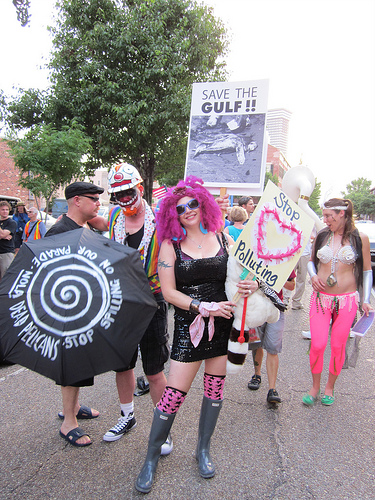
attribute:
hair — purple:
[156, 177, 223, 241]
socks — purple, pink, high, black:
[156, 371, 227, 418]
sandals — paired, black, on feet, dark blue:
[55, 404, 102, 447]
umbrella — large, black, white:
[0, 225, 160, 383]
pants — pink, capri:
[307, 291, 358, 375]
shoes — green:
[302, 389, 336, 409]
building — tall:
[264, 103, 295, 158]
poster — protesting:
[226, 180, 318, 303]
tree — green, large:
[10, 0, 233, 208]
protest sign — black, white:
[223, 178, 314, 313]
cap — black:
[62, 182, 105, 200]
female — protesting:
[299, 196, 373, 405]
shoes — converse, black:
[102, 408, 175, 456]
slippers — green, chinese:
[300, 388, 334, 411]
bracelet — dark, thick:
[187, 297, 201, 318]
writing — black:
[231, 237, 279, 290]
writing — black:
[271, 188, 300, 224]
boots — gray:
[134, 398, 221, 494]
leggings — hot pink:
[307, 286, 359, 378]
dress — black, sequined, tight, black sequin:
[165, 238, 231, 361]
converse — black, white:
[103, 408, 177, 457]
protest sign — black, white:
[183, 77, 271, 196]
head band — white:
[321, 202, 350, 214]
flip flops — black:
[57, 403, 99, 449]